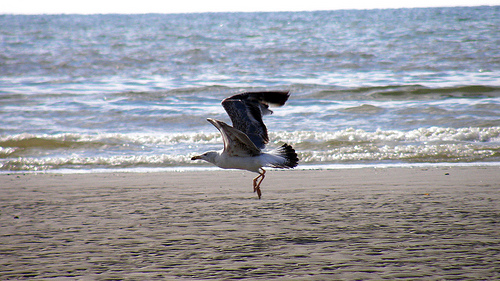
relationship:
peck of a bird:
[188, 147, 205, 163] [190, 82, 336, 210]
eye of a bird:
[202, 153, 214, 158] [185, 79, 313, 210]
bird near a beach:
[187, 85, 303, 202] [1, 13, 499, 278]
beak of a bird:
[188, 152, 203, 162] [189, 89, 299, 200]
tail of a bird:
[272, 137, 298, 172] [189, 89, 299, 200]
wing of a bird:
[222, 88, 294, 152] [189, 89, 299, 200]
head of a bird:
[195, 148, 215, 161] [189, 89, 299, 200]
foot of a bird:
[251, 177, 259, 192] [189, 89, 299, 200]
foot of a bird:
[254, 187, 261, 200] [189, 89, 299, 200]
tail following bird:
[267, 142, 302, 171] [209, 94, 282, 255]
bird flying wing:
[189, 89, 299, 200] [205, 117, 258, 156]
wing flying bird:
[205, 117, 258, 156] [189, 89, 299, 200]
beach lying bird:
[1, 166, 498, 278] [189, 89, 299, 200]